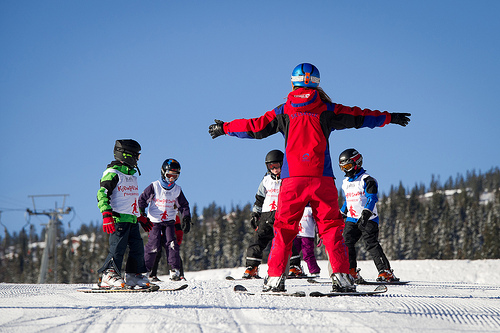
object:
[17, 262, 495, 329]
snow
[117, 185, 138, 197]
logo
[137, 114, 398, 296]
ad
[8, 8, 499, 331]
photo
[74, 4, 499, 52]
ad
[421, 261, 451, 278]
more white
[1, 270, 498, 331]
pile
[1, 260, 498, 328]
white (snow)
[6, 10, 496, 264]
background